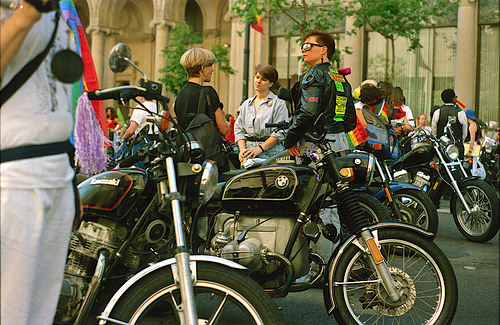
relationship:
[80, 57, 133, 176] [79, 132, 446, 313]
flag on motorcycle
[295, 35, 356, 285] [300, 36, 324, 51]
rider wears sunglasses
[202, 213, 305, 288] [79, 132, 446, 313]
gas tank on motorcycle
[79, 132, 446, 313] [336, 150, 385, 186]
motorcycle has headlight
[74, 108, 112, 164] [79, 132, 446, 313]
pompom on motorcycle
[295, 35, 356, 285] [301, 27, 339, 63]
rider has head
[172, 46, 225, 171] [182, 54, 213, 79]
woman has head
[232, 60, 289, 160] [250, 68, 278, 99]
person has head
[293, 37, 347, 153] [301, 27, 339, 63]
person has head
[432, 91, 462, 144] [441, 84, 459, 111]
person has head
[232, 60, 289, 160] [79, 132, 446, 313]
woman near motorcycle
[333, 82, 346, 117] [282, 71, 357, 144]
patches on jacket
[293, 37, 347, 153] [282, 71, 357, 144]
woman wears jacket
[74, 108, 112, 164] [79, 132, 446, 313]
streamers on motorcycle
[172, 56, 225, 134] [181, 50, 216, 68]
woman has blonde hair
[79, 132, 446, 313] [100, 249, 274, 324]
motorcycle has tire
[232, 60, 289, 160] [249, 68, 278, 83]
woman has brown hair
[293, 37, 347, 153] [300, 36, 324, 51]
woman has sunglasses